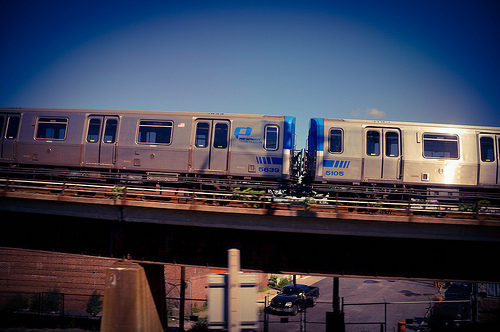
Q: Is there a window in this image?
A: Yes, there is a window.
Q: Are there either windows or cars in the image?
A: Yes, there is a window.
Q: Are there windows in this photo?
A: Yes, there is a window.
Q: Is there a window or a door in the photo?
A: Yes, there is a window.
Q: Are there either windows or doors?
A: Yes, there is a window.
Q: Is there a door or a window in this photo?
A: Yes, there is a window.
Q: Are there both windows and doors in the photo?
A: Yes, there are both a window and a door.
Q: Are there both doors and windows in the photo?
A: Yes, there are both a window and a door.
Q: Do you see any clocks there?
A: No, there are no clocks.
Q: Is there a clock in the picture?
A: No, there are no clocks.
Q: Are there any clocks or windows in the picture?
A: Yes, there is a window.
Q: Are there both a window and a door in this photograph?
A: Yes, there are both a window and a door.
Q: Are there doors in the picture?
A: Yes, there are doors.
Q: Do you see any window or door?
A: Yes, there are doors.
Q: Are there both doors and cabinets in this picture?
A: No, there are doors but no cabinets.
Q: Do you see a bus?
A: No, there are no buses.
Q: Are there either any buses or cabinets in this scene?
A: No, there are no buses or cabinets.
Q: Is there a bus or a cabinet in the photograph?
A: No, there are no buses or cabinets.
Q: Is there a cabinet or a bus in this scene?
A: No, there are no buses or cabinets.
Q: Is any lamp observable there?
A: No, there are no lamps.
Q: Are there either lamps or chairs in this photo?
A: No, there are no lamps or chairs.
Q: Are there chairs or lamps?
A: No, there are no lamps or chairs.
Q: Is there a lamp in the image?
A: No, there are no lamps.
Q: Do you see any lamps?
A: No, there are no lamps.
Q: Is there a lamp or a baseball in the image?
A: No, there are no lamps or baseballs.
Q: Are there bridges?
A: Yes, there is a bridge.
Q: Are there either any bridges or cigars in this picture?
A: Yes, there is a bridge.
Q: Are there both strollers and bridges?
A: No, there is a bridge but no strollers.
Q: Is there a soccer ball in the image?
A: No, there are no soccer balls.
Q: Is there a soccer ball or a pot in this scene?
A: No, there are no soccer balls or pots.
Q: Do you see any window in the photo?
A: Yes, there is a window.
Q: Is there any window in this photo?
A: Yes, there is a window.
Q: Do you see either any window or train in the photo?
A: Yes, there is a window.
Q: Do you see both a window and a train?
A: Yes, there are both a window and a train.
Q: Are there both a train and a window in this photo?
A: Yes, there are both a window and a train.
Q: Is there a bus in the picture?
A: No, there are no buses.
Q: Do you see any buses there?
A: No, there are no buses.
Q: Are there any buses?
A: No, there are no buses.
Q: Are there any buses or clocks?
A: No, there are no buses or clocks.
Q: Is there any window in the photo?
A: Yes, there is a window.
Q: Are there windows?
A: Yes, there is a window.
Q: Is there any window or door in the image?
A: Yes, there is a window.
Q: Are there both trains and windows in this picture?
A: Yes, there are both a window and a train.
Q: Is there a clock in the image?
A: No, there are no clocks.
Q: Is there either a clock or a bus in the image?
A: No, there are no clocks or buses.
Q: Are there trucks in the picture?
A: Yes, there is a truck.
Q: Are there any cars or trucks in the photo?
A: Yes, there is a truck.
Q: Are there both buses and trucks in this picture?
A: No, there is a truck but no buses.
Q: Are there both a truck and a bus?
A: No, there is a truck but no buses.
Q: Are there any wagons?
A: No, there are no wagons.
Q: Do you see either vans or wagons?
A: No, there are no wagons or vans.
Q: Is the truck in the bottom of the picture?
A: Yes, the truck is in the bottom of the image.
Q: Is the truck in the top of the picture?
A: No, the truck is in the bottom of the image.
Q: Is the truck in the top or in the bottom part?
A: The truck is in the bottom of the image.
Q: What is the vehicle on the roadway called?
A: The vehicle is a truck.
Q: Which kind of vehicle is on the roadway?
A: The vehicle is a truck.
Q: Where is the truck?
A: The truck is on the roadway.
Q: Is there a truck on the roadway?
A: Yes, there is a truck on the roadway.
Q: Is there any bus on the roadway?
A: No, there is a truck on the roadway.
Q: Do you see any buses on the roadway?
A: No, there is a truck on the roadway.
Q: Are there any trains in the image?
A: Yes, there is a train.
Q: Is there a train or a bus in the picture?
A: Yes, there is a train.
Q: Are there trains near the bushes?
A: Yes, there is a train near the bushes.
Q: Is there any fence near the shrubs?
A: No, there is a train near the shrubs.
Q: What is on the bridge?
A: The train is on the bridge.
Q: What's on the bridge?
A: The train is on the bridge.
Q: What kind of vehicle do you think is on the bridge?
A: The vehicle is a train.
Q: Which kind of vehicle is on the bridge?
A: The vehicle is a train.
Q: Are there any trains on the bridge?
A: Yes, there is a train on the bridge.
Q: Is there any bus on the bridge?
A: No, there is a train on the bridge.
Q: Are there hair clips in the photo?
A: No, there are no hair clips.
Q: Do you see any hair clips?
A: No, there are no hair clips.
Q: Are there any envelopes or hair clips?
A: No, there are no hair clips or envelopes.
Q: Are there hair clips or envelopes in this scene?
A: No, there are no hair clips or envelopes.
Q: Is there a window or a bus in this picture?
A: Yes, there is a window.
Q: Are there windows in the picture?
A: Yes, there is a window.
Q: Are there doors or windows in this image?
A: Yes, there is a window.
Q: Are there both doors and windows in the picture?
A: Yes, there are both a window and a door.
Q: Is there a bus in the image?
A: No, there are no buses.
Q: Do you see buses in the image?
A: No, there are no buses.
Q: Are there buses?
A: No, there are no buses.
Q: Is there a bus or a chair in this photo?
A: No, there are no buses or chairs.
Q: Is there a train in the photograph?
A: Yes, there is a train.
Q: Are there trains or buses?
A: Yes, there is a train.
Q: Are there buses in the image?
A: No, there are no buses.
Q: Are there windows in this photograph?
A: Yes, there is a window.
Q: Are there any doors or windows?
A: Yes, there is a window.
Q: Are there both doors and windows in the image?
A: Yes, there are both a window and a door.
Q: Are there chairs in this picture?
A: No, there are no chairs.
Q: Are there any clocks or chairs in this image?
A: No, there are no chairs or clocks.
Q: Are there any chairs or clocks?
A: No, there are no chairs or clocks.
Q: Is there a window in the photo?
A: Yes, there is a window.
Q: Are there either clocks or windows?
A: Yes, there is a window.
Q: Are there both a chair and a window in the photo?
A: No, there is a window but no chairs.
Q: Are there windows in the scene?
A: Yes, there is a window.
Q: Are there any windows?
A: Yes, there is a window.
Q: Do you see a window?
A: Yes, there is a window.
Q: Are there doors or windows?
A: Yes, there is a window.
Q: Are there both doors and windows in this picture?
A: Yes, there are both a window and a door.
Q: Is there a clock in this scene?
A: No, there are no clocks.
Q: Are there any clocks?
A: No, there are no clocks.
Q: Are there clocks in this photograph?
A: No, there are no clocks.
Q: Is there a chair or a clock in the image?
A: No, there are no clocks or chairs.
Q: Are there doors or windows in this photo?
A: Yes, there is a window.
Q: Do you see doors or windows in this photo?
A: Yes, there is a window.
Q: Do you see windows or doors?
A: Yes, there is a window.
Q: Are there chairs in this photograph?
A: No, there are no chairs.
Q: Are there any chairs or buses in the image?
A: No, there are no chairs or buses.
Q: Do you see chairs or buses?
A: No, there are no chairs or buses.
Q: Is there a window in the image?
A: Yes, there is a window.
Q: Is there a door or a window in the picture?
A: Yes, there is a window.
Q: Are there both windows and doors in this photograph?
A: Yes, there are both a window and a door.